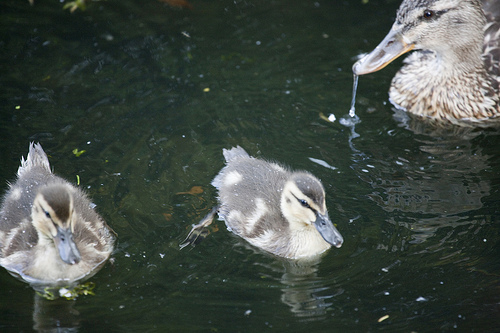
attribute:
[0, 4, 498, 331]
water — murky, dirty, green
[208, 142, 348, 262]
duck — small, grey, feathery, brown, baby, black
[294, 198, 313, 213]
eye — black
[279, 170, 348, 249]
head — tan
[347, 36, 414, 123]
beak — dripping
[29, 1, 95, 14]
leaves — floating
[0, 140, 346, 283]
ducks — babies, little, three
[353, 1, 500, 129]
duck — mother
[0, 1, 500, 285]
ducks — three